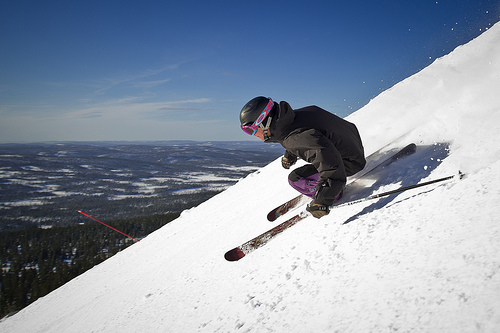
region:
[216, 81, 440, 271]
skier on snowy mountain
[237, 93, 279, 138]
goggles and head covering on a skier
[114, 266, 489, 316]
white snow on ground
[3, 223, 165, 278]
green trees at bottom of mountain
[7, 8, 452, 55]
blue sky in the distance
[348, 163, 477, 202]
ski pole used by skier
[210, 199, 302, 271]
front part of skiis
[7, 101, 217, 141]
white clouds in the sky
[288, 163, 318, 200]
purple and black ski pants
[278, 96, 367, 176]
black ski jacket on skier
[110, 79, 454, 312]
skier on steep hill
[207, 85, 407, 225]
skier has black jacket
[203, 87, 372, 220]
skier has purple and black pants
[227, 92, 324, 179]
skier has black hat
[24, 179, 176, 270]
red pole on hill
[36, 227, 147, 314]
trees at bottom of hill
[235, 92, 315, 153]
skier has pink goggles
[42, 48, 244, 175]
blue hazy sky above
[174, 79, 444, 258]
skier leaning to one side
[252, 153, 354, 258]
skier has black gloves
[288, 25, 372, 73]
part of the sky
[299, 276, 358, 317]
part of some snow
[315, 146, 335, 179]
part of a black jacket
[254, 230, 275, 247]
part of a skating board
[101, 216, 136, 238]
part of a hooker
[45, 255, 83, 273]
overview of some trees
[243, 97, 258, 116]
top of a head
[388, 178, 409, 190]
part of a black hooker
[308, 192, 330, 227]
left hand of the skater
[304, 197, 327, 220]
Left hand of a person skiing down a hill.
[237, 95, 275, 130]
Black helmet on a person skiing down a hill.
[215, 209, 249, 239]
White snow on the ground in front of a skier.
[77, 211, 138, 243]
Thin red pole sticking out of the snow.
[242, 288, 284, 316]
Snow on the ground near a skier.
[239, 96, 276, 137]
Purple and blue goggles on a skiers face.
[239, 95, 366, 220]
Skier skiing down a hill with a black helmet on.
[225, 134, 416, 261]
Skis on a person skiing down a snowy hill.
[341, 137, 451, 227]
Shadow of a person on skis skiing down a snowy hill.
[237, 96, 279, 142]
Head of a person skiing down a hill.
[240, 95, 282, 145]
Head of a person on skis with black helmet on.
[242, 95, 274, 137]
Purple and blue goggles on a person skiing's face.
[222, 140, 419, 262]
Left ski on the foot of a person skiing down a steep hill.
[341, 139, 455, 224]
Shadow of a person skiing down a hill.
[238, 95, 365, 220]
Person skiing down a hill with blue and purple goggles on.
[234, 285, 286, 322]
Lots of white snow on the ground near the skier.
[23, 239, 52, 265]
Many various trees in the distance.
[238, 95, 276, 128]
Black helmet with goggle strap going around it.